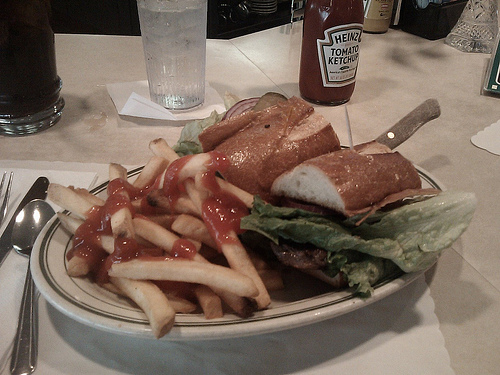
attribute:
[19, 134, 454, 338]
plate — white, round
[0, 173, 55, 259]
knife — silver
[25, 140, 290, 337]
fries — french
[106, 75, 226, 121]
napkin — white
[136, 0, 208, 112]
glass — tall, clear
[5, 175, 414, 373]
placemat — white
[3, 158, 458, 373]
napkin — white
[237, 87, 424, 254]
sandwich — cut in half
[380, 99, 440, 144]
handle — wood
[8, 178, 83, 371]
spoons — silver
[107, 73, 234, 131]
napkin — beverage, white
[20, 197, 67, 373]
silver spoon — silver 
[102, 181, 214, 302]
fries — french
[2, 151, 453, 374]
place mat — white